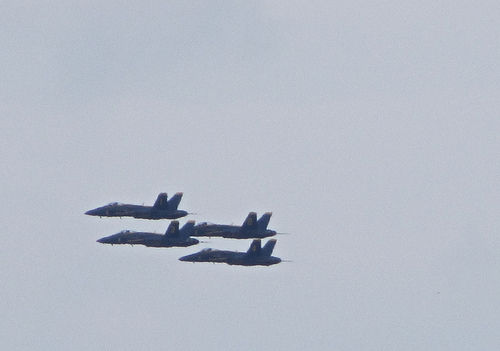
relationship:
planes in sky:
[177, 236, 285, 265] [39, 74, 494, 329]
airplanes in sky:
[86, 188, 190, 220] [39, 74, 494, 329]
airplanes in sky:
[73, 188, 319, 280] [39, 74, 494, 329]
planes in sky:
[92, 190, 322, 277] [39, 74, 494, 329]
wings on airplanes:
[132, 199, 190, 216] [86, 188, 190, 220]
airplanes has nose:
[86, 188, 190, 220] [79, 203, 103, 219]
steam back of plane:
[276, 228, 295, 241] [187, 218, 305, 248]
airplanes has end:
[86, 188, 190, 220] [173, 195, 189, 226]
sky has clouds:
[39, 74, 494, 329] [142, 42, 393, 139]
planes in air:
[177, 236, 285, 265] [19, 71, 468, 264]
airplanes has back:
[86, 188, 190, 220] [181, 203, 195, 228]